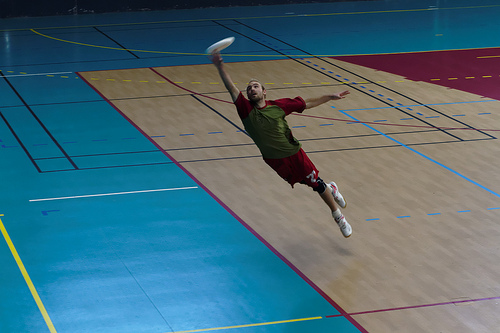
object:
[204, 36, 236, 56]
frisbee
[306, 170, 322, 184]
design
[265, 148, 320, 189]
shorts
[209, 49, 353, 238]
man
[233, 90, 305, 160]
shirt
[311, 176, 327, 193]
knee guard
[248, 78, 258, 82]
hair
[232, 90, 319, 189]
dress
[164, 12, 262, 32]
air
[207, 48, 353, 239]
mid-air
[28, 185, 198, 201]
line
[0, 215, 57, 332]
line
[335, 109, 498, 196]
line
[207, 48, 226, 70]
hands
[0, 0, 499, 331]
ground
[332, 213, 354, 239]
shoe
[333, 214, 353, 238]
left foot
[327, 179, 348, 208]
shoe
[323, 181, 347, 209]
right foot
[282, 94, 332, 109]
left arm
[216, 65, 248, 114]
right arm